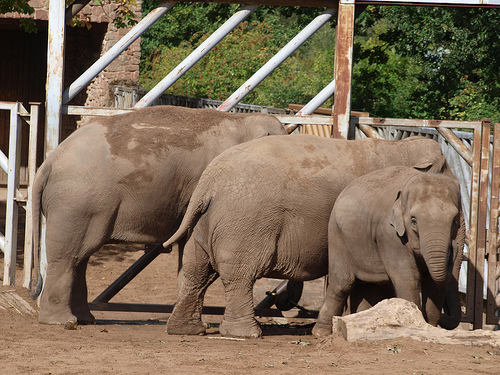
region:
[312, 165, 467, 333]
A small elephant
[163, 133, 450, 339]
A large elephant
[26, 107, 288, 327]
A large elephant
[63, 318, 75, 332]
some excrement on the ground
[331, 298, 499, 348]
A large log on the ground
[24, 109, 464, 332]
A trio of elephants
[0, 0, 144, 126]
A large stone wall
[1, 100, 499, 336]
A metal fence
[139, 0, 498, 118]
A wooded area behind a fence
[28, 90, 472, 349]
elephants standing behind fence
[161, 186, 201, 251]
tail of an elephant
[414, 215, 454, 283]
trunk of baby elephant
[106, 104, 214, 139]
dirt on elephant's back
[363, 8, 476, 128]
green leaves on trees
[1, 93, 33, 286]
wooden gate behind elephants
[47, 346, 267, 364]
dirt ground where elephant's are standing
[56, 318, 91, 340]
feces from an elephant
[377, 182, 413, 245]
left ear of an elephant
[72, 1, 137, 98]
brick building behind elephants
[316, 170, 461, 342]
a baby elephant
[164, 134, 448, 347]
an adult elephant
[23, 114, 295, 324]
an adult elephant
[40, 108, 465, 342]
two adult and one baby elephant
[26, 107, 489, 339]
three elephants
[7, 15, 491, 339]
three elephants inside of an enclosure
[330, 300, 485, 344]
a log in an elephant enclosure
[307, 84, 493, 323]
a rusty metal gate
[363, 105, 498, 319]
a rusty metal gate for an elephant enclosure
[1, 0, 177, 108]
a brick building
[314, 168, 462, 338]
small baby elephant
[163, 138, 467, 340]
elephant in the middle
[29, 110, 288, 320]
larger elephant at the end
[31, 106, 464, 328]
three elephants together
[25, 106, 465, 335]
elephants in an enclosure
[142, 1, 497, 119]
green trees in the distance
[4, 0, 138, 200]
brick structure on the left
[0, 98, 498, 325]
wooden fence holding in elephants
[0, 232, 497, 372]
dirt ground under elephants feet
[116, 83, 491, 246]
outer fencing area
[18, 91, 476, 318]
Three elephants standing together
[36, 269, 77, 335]
Hear shape on big elephants leg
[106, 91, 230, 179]
Wet mud on the back of elephant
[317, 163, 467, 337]
Infant elephant facing away from the others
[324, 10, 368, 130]
Rusty post for part of the pen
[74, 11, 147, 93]
Red brick wall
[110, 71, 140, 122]
Lantern on brick wall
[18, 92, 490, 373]
Three different size elephants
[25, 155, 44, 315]
The long tail of an elephant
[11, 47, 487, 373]
Three elephants in a pen cooling off